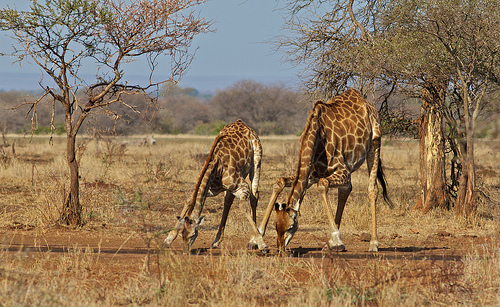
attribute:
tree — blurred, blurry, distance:
[153, 78, 211, 135]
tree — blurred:
[206, 78, 303, 137]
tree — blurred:
[80, 82, 156, 131]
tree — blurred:
[4, 90, 64, 132]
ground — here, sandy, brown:
[2, 131, 498, 302]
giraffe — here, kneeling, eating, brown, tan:
[249, 87, 395, 252]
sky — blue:
[2, 1, 466, 91]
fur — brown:
[274, 210, 289, 247]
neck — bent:
[190, 156, 216, 217]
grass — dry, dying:
[0, 250, 497, 300]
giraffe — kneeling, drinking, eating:
[161, 117, 271, 253]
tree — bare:
[1, 3, 204, 225]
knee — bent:
[272, 176, 285, 193]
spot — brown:
[227, 147, 241, 159]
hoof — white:
[256, 245, 270, 255]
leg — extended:
[225, 167, 272, 258]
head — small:
[175, 208, 201, 250]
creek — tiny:
[3, 245, 461, 260]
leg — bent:
[249, 171, 294, 247]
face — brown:
[272, 209, 297, 254]